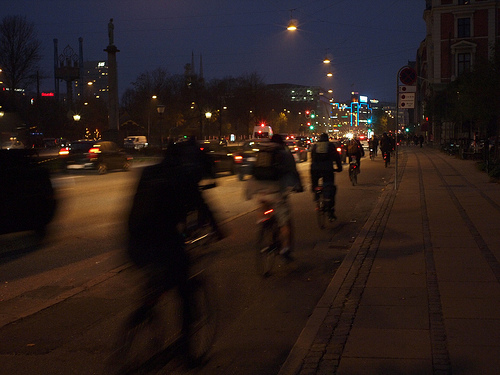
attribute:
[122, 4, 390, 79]
sky — blue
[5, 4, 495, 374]
picture — at night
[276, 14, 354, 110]
lights — in a row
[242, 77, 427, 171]
buildings — in the distance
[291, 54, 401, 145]
lights — on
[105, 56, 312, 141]
trees — distant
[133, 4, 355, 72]
sky — clear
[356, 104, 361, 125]
lights — neon 